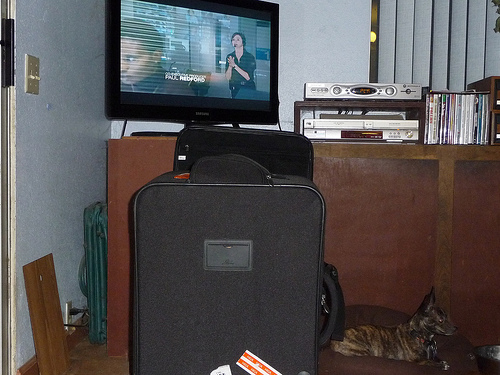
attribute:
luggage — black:
[125, 150, 326, 373]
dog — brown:
[331, 290, 456, 362]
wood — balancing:
[12, 219, 81, 371]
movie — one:
[446, 89, 469, 146]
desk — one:
[111, 121, 485, 351]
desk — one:
[107, 110, 491, 332]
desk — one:
[109, 130, 499, 358]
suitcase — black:
[130, 168, 326, 371]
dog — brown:
[341, 292, 450, 362]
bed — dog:
[321, 296, 436, 374]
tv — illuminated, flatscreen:
[99, 0, 284, 129]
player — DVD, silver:
[300, 118, 421, 140]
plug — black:
[65, 296, 87, 327]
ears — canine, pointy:
[420, 284, 444, 324]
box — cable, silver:
[300, 77, 423, 96]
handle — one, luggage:
[316, 268, 352, 356]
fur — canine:
[366, 339, 409, 349]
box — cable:
[308, 75, 428, 98]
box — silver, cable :
[303, 80, 420, 101]